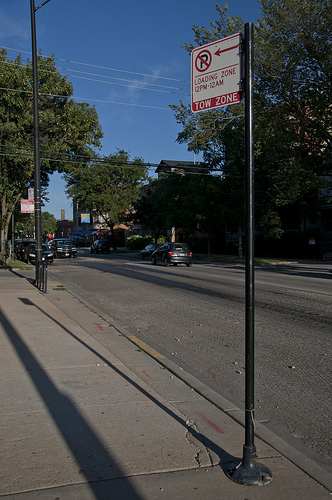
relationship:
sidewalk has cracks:
[24, 287, 218, 469] [182, 420, 216, 466]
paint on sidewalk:
[95, 319, 233, 448] [0, 252, 213, 408]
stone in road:
[288, 363, 296, 369] [41, 245, 332, 469]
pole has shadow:
[238, 37, 263, 474] [34, 391, 117, 456]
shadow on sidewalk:
[34, 391, 117, 456] [20, 282, 205, 475]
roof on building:
[155, 158, 208, 172] [150, 157, 215, 183]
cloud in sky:
[103, 62, 168, 110] [95, 26, 159, 64]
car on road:
[150, 241, 193, 267] [128, 258, 182, 289]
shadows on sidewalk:
[15, 293, 244, 475] [5, 262, 320, 488]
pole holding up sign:
[238, 21, 259, 474] [186, 28, 248, 123]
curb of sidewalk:
[273, 253, 326, 272] [5, 262, 320, 488]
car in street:
[148, 239, 195, 269] [63, 249, 328, 403]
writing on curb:
[122, 329, 170, 364] [98, 335, 190, 398]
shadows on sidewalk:
[0, 292, 237, 496] [0, 279, 236, 455]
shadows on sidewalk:
[193, 245, 329, 262] [191, 245, 330, 265]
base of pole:
[224, 453, 272, 486] [244, 19, 258, 447]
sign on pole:
[191, 32, 243, 114] [226, 21, 271, 487]